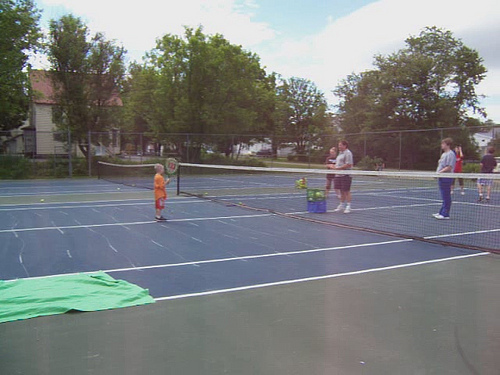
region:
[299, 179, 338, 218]
a basket of tennis balls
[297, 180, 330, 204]
this is a basket of balls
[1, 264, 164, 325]
this is a blanket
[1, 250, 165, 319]
a green blanket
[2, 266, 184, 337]
a green blanket on a tennis court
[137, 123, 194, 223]
he is holding a racket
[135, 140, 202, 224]
this boy is holding a tennis racket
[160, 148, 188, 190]
this is a Wilson brand tennis racket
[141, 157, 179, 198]
his shirt is orange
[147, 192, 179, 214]
his shorts are red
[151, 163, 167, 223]
boy on the tennis court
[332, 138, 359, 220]
man on the tennis court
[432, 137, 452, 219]
woman on the tennis court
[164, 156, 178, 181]
boy holding tennis racquet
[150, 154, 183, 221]
boy playing tennis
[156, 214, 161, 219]
shoe on the boy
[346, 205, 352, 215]
shoe on the man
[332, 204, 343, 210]
shoe on the man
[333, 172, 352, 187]
shorts on the man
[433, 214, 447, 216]
shoes on the woman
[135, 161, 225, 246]
boy wearing organge shirt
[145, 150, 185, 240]
boy wearing red shorts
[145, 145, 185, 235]
boy holding a racket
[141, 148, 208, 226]
boy standing on a tennis court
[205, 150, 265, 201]
net on a tennis court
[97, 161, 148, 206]
net on a tennis court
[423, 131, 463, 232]
man wearing a gray shirt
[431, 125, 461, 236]
man wearing blue jeans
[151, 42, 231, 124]
trees next to court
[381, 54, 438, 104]
trees near a court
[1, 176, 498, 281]
Regular tennis court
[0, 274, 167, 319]
Green tarp lying on tennis court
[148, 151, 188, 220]
Child with tennis racket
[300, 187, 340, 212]
Large container of tennis balls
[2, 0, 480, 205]
Several trees with green leaves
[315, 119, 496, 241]
Adults standing on tennis court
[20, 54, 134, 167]
Building with shingled roof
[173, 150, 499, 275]
Net on tennis court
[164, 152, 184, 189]
Wilson brand tennis racket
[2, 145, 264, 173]
Grass next to tennis court